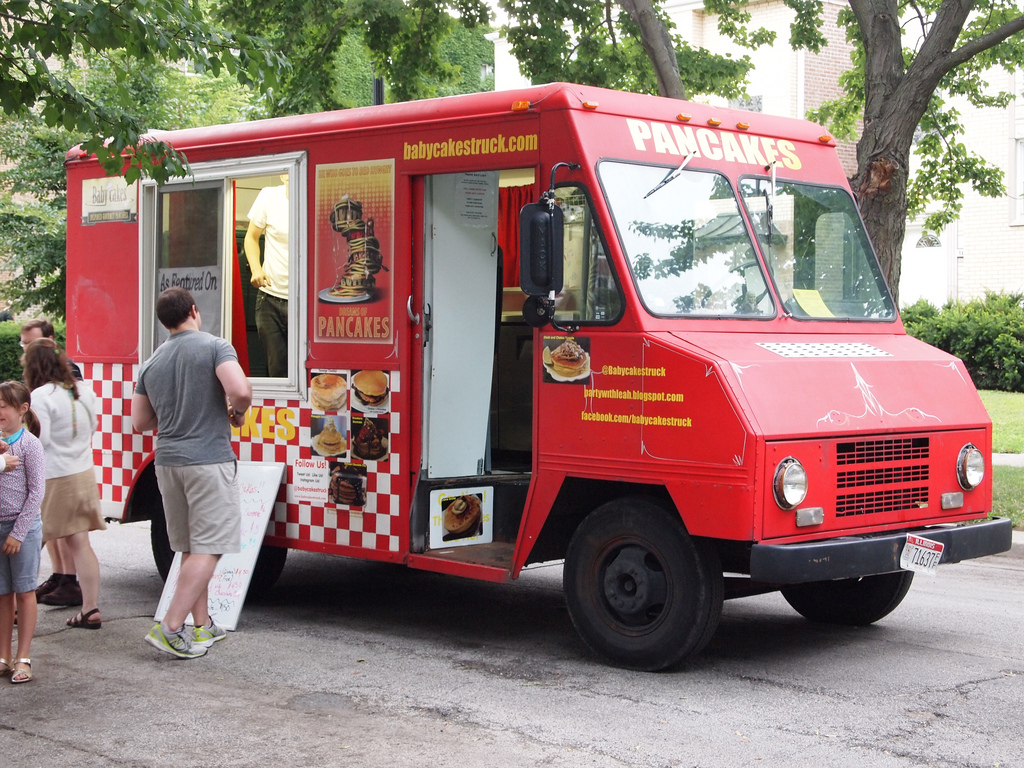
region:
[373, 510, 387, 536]
white square on red truck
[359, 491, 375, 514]
white square on red truck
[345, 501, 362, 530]
white square on red truck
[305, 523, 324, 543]
white square on red truck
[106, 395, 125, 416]
white square on red truck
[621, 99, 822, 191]
letters are yellow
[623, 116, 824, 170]
letters on front of truck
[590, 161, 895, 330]
windshield on the truck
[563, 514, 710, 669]
wheel on the truck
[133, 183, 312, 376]
window on side of truck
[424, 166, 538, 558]
door on side of truck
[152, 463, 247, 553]
man is wearing shorts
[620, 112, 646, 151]
yellow letter on the red truck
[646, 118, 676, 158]
yellow letter on the red truck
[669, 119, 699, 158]
yellow letter on the red truck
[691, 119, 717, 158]
yellow letter on the red truck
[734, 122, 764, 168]
yellow letter on the red truck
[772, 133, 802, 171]
yellow letter on the red truck